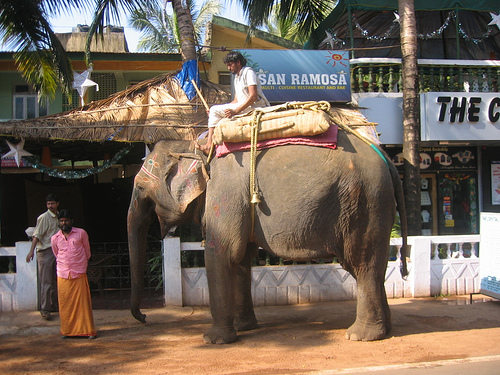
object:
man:
[194, 49, 270, 153]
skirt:
[54, 270, 98, 338]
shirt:
[51, 227, 91, 280]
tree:
[327, 1, 497, 239]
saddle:
[214, 99, 338, 150]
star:
[3, 138, 36, 170]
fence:
[163, 234, 495, 304]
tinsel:
[351, 16, 399, 43]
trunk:
[124, 211, 153, 325]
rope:
[243, 114, 262, 247]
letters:
[435, 96, 452, 123]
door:
[435, 168, 481, 258]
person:
[47, 209, 99, 342]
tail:
[383, 153, 409, 283]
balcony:
[349, 57, 498, 120]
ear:
[164, 150, 210, 213]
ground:
[0, 298, 499, 375]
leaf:
[28, 73, 64, 94]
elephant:
[127, 128, 409, 341]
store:
[2, 55, 478, 306]